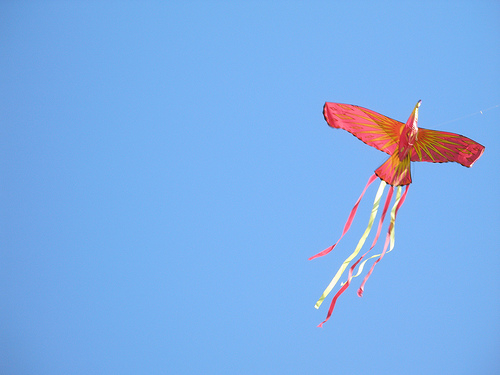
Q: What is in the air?
A: A large kite.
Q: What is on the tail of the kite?
A: Red and white ribbons.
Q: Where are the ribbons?
A: On the kite.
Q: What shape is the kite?
A: Like a bird.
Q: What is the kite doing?
A: Flying in the sky.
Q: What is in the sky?
A: Red and yellow bird kite.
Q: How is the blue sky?
A: Crystal clear.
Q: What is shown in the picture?
A: Tail of a red and yellow kite.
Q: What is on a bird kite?
A: Winds of a red and yellow.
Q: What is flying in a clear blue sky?
A: A kite.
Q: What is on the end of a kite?
A: Streamers.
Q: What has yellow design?
A: A red kite.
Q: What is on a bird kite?
A: Red and yellow ribbons.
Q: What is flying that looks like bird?
A: A kite.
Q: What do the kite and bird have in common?
A: They fly.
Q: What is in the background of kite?
A: Sky.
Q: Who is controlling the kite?
A: Kite flyer.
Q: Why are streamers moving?
A: Air passing through.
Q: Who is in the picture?
A: Nobody.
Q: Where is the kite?
A: Air.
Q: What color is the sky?
A: Blue.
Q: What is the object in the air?
A: Kite.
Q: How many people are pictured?
A: 0.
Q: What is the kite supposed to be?
A: Bird.